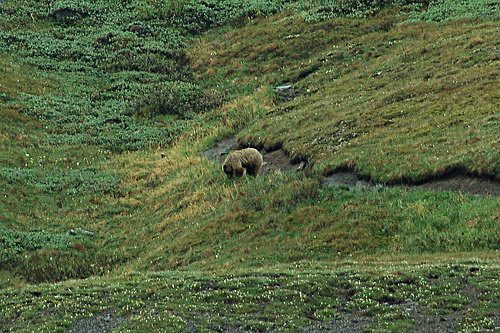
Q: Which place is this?
A: It is a field.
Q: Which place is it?
A: It is a field.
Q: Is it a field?
A: Yes, it is a field.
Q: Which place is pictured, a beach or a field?
A: It is a field.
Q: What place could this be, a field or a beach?
A: It is a field.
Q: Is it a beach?
A: No, it is a field.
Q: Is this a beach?
A: No, it is a field.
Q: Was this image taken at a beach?
A: No, the picture was taken in a field.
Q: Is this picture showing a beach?
A: No, the picture is showing a field.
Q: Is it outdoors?
A: Yes, it is outdoors.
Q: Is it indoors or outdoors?
A: It is outdoors.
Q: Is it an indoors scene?
A: No, it is outdoors.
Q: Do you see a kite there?
A: No, there are no kites.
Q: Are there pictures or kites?
A: No, there are no kites or pictures.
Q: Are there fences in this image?
A: No, there are no fences.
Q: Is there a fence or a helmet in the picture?
A: No, there are no fences or helmets.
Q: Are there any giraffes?
A: No, there are no giraffes.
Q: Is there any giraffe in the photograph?
A: No, there are no giraffes.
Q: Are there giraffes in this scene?
A: No, there are no giraffes.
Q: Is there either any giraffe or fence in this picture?
A: No, there are no giraffes or fences.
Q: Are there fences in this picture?
A: No, there are no fences.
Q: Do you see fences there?
A: No, there are no fences.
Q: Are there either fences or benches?
A: No, there are no fences or benches.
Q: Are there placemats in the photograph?
A: No, there are no placemats.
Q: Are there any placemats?
A: No, there are no placemats.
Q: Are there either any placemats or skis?
A: No, there are no placemats or skis.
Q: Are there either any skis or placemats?
A: No, there are no placemats or skis.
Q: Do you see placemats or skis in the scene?
A: No, there are no placemats or skis.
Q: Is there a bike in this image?
A: No, there are no bikes.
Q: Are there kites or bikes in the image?
A: No, there are no bikes or kites.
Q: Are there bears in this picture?
A: Yes, there is a bear.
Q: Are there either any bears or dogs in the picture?
A: Yes, there is a bear.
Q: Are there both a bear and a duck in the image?
A: No, there is a bear but no ducks.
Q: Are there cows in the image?
A: No, there are no cows.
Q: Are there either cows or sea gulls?
A: No, there are no cows or sea gulls.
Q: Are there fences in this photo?
A: No, there are no fences.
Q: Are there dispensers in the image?
A: No, there are no dispensers.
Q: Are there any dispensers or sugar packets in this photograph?
A: No, there are no dispensers or sugar packets.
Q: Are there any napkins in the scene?
A: No, there are no napkins.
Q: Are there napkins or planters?
A: No, there are no napkins or planters.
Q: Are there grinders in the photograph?
A: No, there are no grinders.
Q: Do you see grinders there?
A: No, there are no grinders.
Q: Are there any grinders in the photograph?
A: No, there are no grinders.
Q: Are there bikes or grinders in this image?
A: No, there are no grinders or bikes.